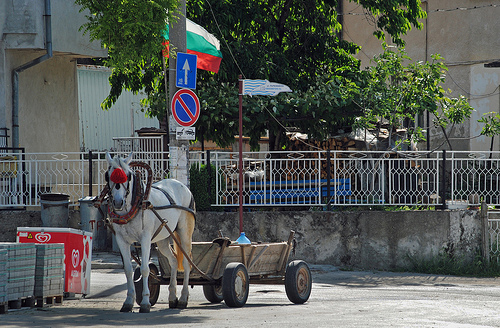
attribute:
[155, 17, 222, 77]
flag — white , green , Red 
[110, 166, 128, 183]
tassle — hanging , red 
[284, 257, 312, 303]
wheel — wheels, black 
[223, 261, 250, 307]
wheel — wheels, black 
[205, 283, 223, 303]
wheel — wheels, black 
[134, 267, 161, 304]
wheel — wheels, black 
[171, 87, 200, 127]
sign — blue , red , traffic 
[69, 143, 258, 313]
horse — white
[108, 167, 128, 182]
flower — red 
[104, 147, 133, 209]
head — horses 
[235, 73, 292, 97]
flag — white 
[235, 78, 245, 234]
pole — red 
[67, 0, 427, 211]
tree — green, large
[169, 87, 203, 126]
sign — white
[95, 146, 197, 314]
horse — Small , white 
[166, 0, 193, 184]
pole — metal 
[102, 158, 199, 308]
horse — still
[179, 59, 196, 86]
arrow — blue , up , pointing , white 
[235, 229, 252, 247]
blue bottle — Top , plastic , blue 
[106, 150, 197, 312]
horse — white , Small 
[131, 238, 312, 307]
wagon — wheels, black , wooden 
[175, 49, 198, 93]
sign — traffic , blue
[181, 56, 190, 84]
arrow — white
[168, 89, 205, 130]
circle line — red , blue 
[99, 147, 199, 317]
white horse — white , Large 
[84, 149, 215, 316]
horse — white 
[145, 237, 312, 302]
wooden trailer — small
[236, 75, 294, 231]
street sign — flagged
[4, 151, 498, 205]
metal fence — white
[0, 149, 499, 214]
fence — metal , white , long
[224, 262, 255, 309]
wheels — black 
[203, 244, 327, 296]
wagon — wooden 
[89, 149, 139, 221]
head — horses 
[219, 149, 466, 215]
fence — white 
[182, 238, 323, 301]
wagon — wood 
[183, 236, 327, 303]
palates — Wood 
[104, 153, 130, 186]
pom pom — red 